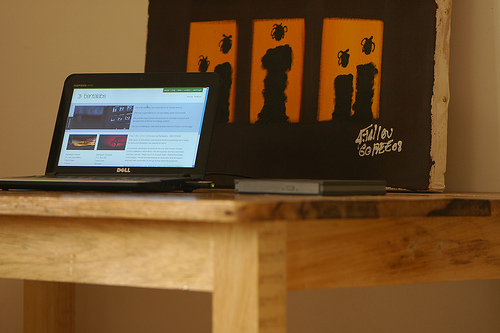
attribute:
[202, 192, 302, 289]
table — large, wooden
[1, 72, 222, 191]
laptop — black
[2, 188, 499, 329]
table — brown, wooden, large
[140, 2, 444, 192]
painting — signed, canvas, orange, black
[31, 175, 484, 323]
table — brown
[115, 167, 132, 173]
dell — word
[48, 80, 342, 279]
laptop — open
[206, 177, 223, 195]
light — lit, green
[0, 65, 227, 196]
laptop — open, opened, black